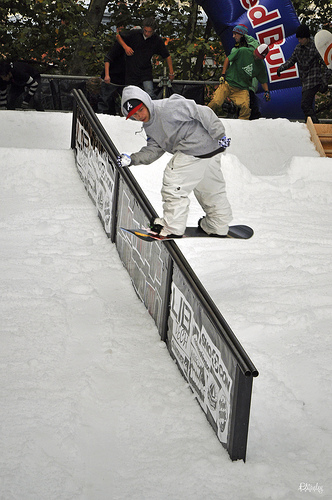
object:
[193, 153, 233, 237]
leg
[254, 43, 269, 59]
hat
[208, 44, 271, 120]
person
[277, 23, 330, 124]
person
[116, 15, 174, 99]
person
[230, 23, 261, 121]
person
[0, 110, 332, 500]
snow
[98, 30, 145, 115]
person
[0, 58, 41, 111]
person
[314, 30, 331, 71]
snowboard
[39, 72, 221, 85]
rail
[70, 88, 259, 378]
rail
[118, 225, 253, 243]
snowboard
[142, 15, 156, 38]
head person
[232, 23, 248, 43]
head person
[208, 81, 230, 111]
leg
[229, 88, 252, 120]
leg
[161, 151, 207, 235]
leg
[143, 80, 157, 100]
leg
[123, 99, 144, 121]
hat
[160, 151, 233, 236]
pants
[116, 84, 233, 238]
man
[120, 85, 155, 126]
head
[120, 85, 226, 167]
jacket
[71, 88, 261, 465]
ramp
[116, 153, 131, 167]
hand